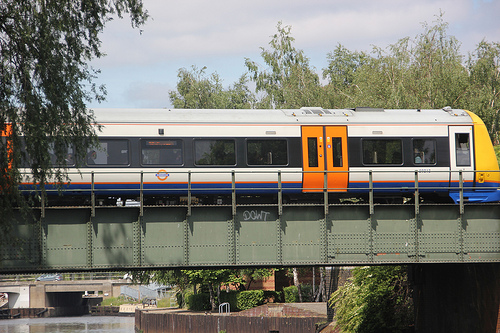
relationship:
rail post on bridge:
[322, 170, 330, 215] [0, 170, 499, 316]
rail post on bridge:
[178, 164, 444, 244] [3, 165, 499, 331]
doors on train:
[287, 110, 362, 219] [15, 101, 465, 238]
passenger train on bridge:
[0, 105, 500, 204] [6, 189, 499, 283]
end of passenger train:
[466, 111, 498, 194] [0, 105, 500, 204]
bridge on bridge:
[0, 202, 500, 272] [0, 202, 500, 272]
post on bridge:
[232, 170, 237, 216] [0, 202, 500, 272]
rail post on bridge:
[183, 169, 198, 219] [0, 202, 500, 272]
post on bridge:
[230, 169, 240, 218] [0, 202, 500, 272]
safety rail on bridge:
[29, 170, 499, 223] [0, 157, 500, 279]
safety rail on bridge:
[0, 170, 500, 217] [0, 202, 500, 272]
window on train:
[246, 138, 288, 165] [20, 102, 495, 197]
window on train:
[249, 137, 289, 167] [2, 103, 498, 207]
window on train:
[344, 127, 425, 195] [11, 90, 498, 220]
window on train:
[195, 138, 234, 164] [2, 103, 498, 207]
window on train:
[143, 148, 184, 167] [2, 103, 498, 207]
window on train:
[61, 135, 133, 167] [2, 103, 498, 207]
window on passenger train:
[307, 137, 319, 167] [2, 105, 499, 210]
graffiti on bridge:
[240, 207, 271, 222] [0, 202, 500, 272]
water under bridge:
[38, 257, 468, 322] [49, 160, 497, 287]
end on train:
[461, 109, 500, 191] [2, 103, 498, 207]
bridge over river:
[0, 202, 500, 272] [108, 318, 186, 329]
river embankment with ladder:
[134, 305, 329, 331] [214, 300, 230, 316]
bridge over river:
[0, 202, 500, 272] [0, 313, 135, 330]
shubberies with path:
[278, 287, 295, 302] [262, 301, 326, 316]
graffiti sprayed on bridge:
[242, 210, 270, 221] [0, 202, 500, 272]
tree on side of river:
[167, 10, 499, 107] [2, 302, 137, 331]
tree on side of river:
[246, 32, 349, 107] [2, 302, 137, 331]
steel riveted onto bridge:
[320, 209, 330, 268] [0, 202, 500, 272]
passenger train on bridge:
[0, 105, 500, 204] [4, 211, 495, 259]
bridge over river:
[4, 211, 495, 259] [47, 316, 120, 328]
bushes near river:
[172, 283, 304, 314] [27, 317, 82, 332]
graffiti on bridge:
[242, 210, 270, 221] [106, 177, 481, 268]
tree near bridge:
[167, 10, 499, 107] [4, 159, 499, 269]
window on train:
[246, 138, 288, 165] [14, 60, 499, 243]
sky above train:
[0, 2, 497, 108] [2, 103, 498, 207]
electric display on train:
[141, 135, 187, 151] [9, 95, 494, 203]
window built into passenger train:
[448, 128, 473, 192] [1, 103, 484, 203]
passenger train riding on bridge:
[0, 105, 500, 204] [0, 202, 500, 272]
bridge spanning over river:
[0, 202, 500, 272] [1, 310, 141, 330]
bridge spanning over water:
[0, 202, 500, 272] [0, 314, 139, 331]